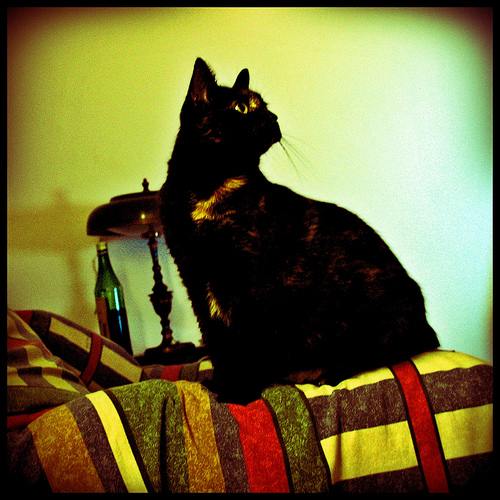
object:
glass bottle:
[92, 239, 128, 361]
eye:
[230, 99, 247, 117]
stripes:
[394, 357, 442, 490]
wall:
[8, 9, 492, 359]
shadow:
[10, 187, 110, 330]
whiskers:
[277, 127, 309, 172]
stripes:
[81, 388, 140, 488]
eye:
[248, 98, 264, 109]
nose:
[264, 113, 279, 122]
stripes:
[8, 422, 41, 487]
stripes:
[422, 362, 494, 406]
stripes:
[51, 313, 143, 382]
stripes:
[99, 343, 148, 376]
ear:
[233, 68, 251, 91]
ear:
[187, 59, 216, 94]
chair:
[0, 304, 497, 492]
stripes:
[225, 394, 289, 492]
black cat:
[158, 57, 440, 405]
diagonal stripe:
[51, 317, 166, 372]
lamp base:
[85, 177, 199, 365]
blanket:
[7, 308, 491, 493]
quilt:
[0, 307, 493, 495]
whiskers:
[264, 124, 323, 181]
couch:
[7, 306, 497, 499]